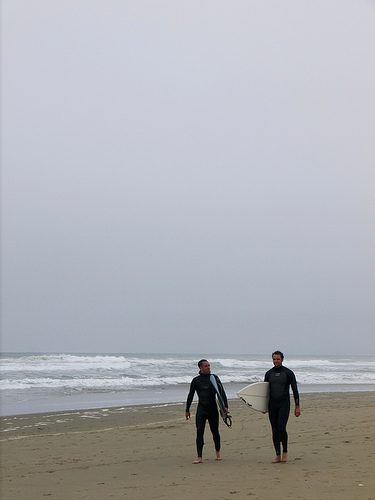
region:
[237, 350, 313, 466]
man on right carrying board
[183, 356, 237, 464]
man of left carrying board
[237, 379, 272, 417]
front end of white surfboard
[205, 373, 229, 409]
front end of blue surfboard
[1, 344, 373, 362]
distant horizon beyond ocean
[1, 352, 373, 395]
white ocean wave crests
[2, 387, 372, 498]
wet brown beach sand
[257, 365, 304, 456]
men's black wet suit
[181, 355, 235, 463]
man walking on beach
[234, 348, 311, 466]
man with board looking forward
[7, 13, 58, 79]
white clouds in blue sky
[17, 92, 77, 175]
white clouds in blue sky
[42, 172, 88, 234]
white clouds in blue sky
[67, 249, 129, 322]
white clouds in blue sky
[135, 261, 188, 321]
white clouds in blue sky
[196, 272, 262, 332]
white clouds in blue sky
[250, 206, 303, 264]
white clouds in blue sky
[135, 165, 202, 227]
white clouds in blue sky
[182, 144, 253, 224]
white clouds in blue sky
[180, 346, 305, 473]
Two surfers on the beach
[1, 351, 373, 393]
Waves in the ocean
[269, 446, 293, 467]
A pair of bare feet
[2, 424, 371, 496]
Footprints on the sand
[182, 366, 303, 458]
Two black colored wetsuits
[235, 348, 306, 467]
A surfer carrying a surfboard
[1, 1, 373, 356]
The sky appears overcast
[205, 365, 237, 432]
Surfboard under a man's arm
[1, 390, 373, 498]
Light brown sand on the beach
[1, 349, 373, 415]
The ocean appears rough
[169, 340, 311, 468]
two men carrying surfboards on the beach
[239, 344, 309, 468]
man carrying a white surfboard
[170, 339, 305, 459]
two men wearing black wet suits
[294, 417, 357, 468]
footprints on the beach sand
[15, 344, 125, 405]
large waves crashing to shore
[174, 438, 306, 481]
two men walking barefoot on the beach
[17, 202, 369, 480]
photograph taken at the beach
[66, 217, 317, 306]
clear sky with no clouds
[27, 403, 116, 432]
sea foam on sandy beach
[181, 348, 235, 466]
man carrying a blue surfboard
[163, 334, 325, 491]
two men wearing black wet suit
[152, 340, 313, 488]
two men carrying surfboards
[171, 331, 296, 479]
two men carrying surfboards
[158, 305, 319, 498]
two men carrying surfboards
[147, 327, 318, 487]
two men carrying surfboards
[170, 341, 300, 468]
two men carrying surfboards